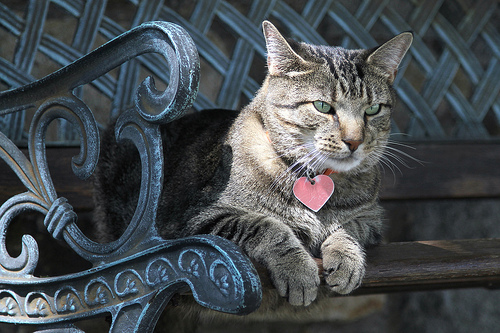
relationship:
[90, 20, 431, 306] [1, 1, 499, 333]
tabby cat lying on bench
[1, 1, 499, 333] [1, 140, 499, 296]
bench has seat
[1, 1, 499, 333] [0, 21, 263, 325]
bench has arm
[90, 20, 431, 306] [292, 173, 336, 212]
tabby cat wearing tag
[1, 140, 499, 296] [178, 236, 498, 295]
seat has slat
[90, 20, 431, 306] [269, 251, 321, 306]
tabby cat has paw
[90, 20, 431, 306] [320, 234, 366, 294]
tabby cat has paw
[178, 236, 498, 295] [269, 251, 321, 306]
slat under paw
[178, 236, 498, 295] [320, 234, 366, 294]
slat under paw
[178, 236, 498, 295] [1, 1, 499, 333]
slat at front of bench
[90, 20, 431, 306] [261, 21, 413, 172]
tabby cat has head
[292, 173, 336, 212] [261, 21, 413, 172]
tag under head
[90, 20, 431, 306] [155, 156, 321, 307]
tabby cat has leg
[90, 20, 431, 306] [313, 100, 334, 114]
tabby cat has eye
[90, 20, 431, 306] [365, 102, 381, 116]
tabby cat has eye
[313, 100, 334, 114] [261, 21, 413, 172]
eye part of head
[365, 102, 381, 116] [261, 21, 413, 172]
eye part of head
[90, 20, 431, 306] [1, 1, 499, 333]
tabby cat sitting on bench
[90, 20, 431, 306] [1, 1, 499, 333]
tabby cat on top of bench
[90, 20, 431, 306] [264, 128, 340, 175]
tabby cat wears collar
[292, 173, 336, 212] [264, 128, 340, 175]
tag hanging from collar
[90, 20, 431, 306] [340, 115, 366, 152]
tabby cat has nose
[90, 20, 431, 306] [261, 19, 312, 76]
tabby cat has ear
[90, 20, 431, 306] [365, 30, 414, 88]
tabby cat has ear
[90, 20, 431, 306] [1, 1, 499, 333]
tabby cat resting on bench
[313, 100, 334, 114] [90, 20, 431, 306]
eye of tabby cat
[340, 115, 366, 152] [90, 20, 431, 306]
nose of tabby cat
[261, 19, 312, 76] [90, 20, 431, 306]
ear of tabby cat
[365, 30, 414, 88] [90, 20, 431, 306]
ear of tabby cat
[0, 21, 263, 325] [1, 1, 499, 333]
arm on side of bench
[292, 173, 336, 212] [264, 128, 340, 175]
tag attached to collar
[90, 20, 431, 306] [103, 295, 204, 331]
tabby cat has tail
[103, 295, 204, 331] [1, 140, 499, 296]
tail underneath seat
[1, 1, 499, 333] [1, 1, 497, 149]
bench has back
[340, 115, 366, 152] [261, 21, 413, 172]
nose on front of head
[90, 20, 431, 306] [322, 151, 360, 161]
tabby cat has mouth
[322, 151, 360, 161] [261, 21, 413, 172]
mouth on front of head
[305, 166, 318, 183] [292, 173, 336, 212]
loop attached to tag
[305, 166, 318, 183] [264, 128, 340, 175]
loop attached to collar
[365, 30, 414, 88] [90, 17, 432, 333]
ear on tabby cat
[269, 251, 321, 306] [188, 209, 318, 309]
paw on cat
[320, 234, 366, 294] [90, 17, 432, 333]
paw on tabby cat